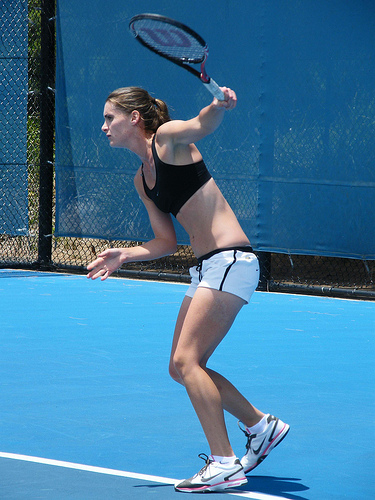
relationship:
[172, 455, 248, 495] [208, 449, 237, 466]
shoe with sock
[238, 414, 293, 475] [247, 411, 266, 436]
shoe with sock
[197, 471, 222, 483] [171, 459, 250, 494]
logo on side of shoe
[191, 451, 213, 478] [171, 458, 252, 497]
laces on sneakers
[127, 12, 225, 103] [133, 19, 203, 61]
racket with mesh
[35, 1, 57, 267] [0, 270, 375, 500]
fence post on court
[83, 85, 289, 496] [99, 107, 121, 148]
human with face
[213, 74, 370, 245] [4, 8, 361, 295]
tarp on fence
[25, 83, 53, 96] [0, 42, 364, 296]
hook on fence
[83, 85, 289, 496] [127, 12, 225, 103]
human holding racket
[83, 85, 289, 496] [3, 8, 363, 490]
human playing tennis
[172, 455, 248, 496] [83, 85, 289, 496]
shoe on human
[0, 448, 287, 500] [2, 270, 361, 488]
boundary painted court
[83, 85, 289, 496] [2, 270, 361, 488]
human on court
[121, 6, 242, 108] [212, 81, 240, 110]
racket in hand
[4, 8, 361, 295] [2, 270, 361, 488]
fence at court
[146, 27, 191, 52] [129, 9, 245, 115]
w on racket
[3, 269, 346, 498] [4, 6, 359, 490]
ground of court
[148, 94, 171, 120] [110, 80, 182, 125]
ponytail in hair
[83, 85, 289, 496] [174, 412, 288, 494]
human has shoes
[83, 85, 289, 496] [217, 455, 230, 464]
human has symbol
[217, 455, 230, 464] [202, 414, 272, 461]
symbol on socks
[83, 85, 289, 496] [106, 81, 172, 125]
human has hair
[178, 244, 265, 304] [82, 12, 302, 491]
shorts worn human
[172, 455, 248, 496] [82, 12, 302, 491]
shoe worn human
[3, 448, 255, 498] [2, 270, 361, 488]
boundary on court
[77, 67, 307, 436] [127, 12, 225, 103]
human with racket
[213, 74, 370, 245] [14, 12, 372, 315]
tarp on fence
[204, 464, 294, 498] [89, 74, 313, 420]
shadow under player